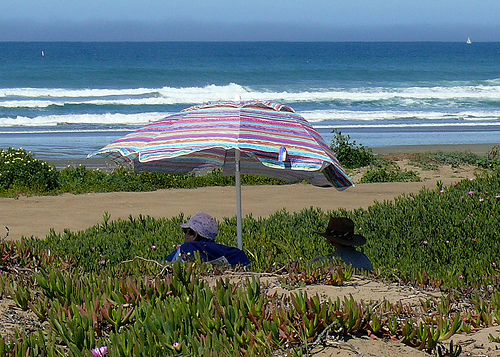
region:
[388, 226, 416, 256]
part of a swamp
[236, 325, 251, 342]
part of a plantation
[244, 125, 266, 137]
part of an umbrella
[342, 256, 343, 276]
back of a man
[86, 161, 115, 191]
part of a shore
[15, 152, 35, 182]
part of the bush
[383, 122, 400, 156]
part of the lake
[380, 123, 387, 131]
part of the beach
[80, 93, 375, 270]
people sitting under an umbrella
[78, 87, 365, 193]
multi colored striped umbrella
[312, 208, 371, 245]
brown cowboy hat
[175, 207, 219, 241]
white ball cap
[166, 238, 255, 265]
blue shirt of person sitting under umbrella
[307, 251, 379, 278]
shirt of person wearing cowboy hat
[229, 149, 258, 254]
pole holding up umbrella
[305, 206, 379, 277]
person the right sitting under umbrella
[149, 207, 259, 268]
person on the left sitting under umbrella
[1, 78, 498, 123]
waves crashing towards shore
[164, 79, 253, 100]
waves covered in white sea foam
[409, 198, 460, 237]
green grass growing on ground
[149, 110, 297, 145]
design on side of umbrella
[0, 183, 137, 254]
path covered in sand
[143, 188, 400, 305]
people sitting under umbrella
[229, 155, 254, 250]
white metal umbrella pole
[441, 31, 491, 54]
white sail boat on water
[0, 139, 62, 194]
bush covered in white buds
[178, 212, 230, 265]
person in white hat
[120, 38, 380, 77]
calm surface of water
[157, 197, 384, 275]
2 people enjoying a day at beach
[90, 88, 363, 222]
multied colored sun umbrella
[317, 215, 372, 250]
cowboy hat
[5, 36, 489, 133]
blue waters of ocean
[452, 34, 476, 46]
white sails of a sailboat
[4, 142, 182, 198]
green vegeation on shore line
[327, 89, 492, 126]
white surf of the waves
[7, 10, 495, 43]
blue skies above ocean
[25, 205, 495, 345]
vegation surrounding the people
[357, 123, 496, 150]
wet sand of the shore line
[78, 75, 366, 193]
the umbrella is open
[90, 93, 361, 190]
the umbrella is striped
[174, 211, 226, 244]
the cap is white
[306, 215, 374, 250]
the hat is brown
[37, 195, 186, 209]
the ground is brown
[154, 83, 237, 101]
the water is white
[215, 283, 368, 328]
the aloe is green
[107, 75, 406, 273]
the men are under the umbrella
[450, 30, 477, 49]
the sailboat is white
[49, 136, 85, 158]
the beach is wet